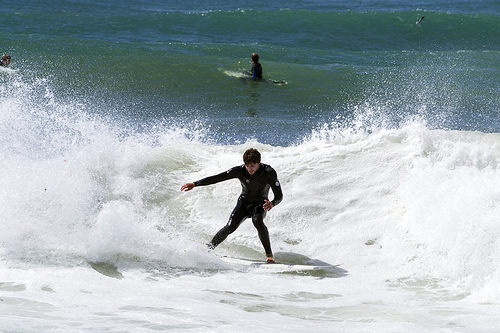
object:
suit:
[189, 162, 285, 266]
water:
[49, 108, 155, 305]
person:
[176, 147, 316, 262]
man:
[246, 52, 269, 80]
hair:
[242, 147, 263, 167]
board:
[210, 250, 343, 274]